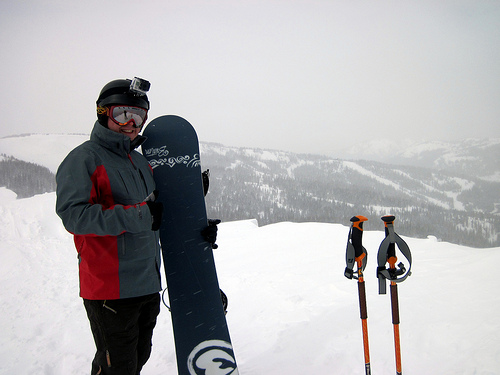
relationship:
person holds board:
[47, 61, 173, 372] [139, 114, 238, 374]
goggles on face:
[107, 102, 149, 126] [105, 116, 142, 140]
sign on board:
[149, 145, 209, 172] [134, 105, 295, 372]